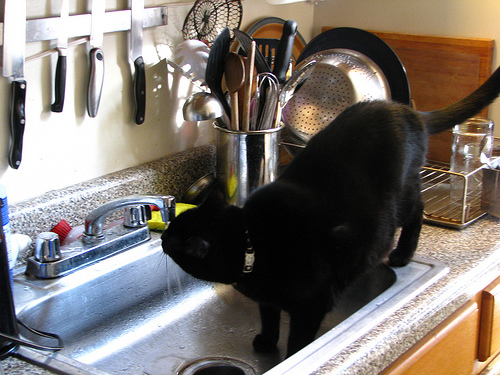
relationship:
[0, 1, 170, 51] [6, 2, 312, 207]
bar on wall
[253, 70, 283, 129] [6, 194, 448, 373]
utensil by sink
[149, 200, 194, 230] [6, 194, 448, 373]
sponge in back corner sink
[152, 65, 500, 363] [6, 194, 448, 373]
cat in sink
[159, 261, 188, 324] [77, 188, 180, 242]
water in faucet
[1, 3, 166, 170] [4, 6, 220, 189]
knives on wall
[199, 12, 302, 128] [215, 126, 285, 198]
utensils in holder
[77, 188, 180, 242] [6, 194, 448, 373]
faucet on sink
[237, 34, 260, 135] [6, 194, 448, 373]
utensil by sink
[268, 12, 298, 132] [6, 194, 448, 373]
utensil by sink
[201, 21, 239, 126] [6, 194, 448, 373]
utensil by sink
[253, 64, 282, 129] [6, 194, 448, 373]
utensil by sink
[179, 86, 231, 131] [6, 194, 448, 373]
utensil by sink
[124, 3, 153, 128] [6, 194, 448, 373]
utensil by sink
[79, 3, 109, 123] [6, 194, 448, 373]
utensil by sink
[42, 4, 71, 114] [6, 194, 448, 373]
utensil by sink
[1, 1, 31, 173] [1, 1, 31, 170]
implement used to implement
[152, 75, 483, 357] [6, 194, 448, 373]
cat in sink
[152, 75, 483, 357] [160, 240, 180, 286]
cat drinking water